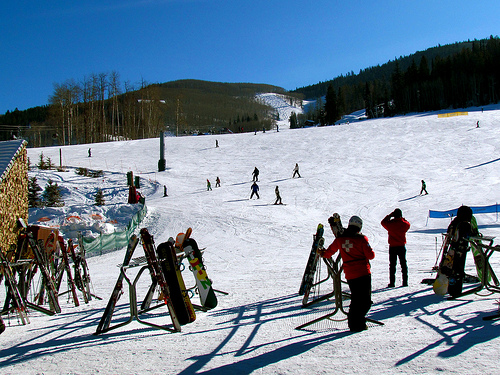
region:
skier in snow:
[267, 180, 287, 208]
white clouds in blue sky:
[134, 25, 161, 42]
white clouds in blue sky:
[287, 37, 342, 82]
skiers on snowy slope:
[185, 153, 307, 223]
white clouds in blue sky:
[327, 9, 355, 40]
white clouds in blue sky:
[172, 16, 209, 53]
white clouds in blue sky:
[124, 22, 161, 54]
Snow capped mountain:
[346, 129, 391, 177]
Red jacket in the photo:
[328, 223, 376, 275]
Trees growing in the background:
[325, 58, 441, 104]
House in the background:
[0, 132, 45, 231]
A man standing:
[315, 184, 378, 331]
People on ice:
[200, 143, 373, 211]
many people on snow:
[162, 125, 490, 355]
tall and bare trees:
[99, 86, 261, 137]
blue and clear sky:
[229, 1, 351, 68]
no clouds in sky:
[222, 14, 379, 106]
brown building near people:
[0, 139, 37, 229]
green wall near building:
[76, 169, 125, 276]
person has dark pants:
[337, 198, 372, 334]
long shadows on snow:
[206, 307, 343, 373]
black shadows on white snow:
[173, 303, 321, 374]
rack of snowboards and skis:
[85, 218, 230, 348]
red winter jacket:
[376, 211, 415, 250]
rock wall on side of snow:
[0, 135, 30, 285]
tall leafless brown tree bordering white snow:
[45, 70, 165, 147]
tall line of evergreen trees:
[315, 31, 495, 126]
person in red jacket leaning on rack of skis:
[291, 207, 381, 342]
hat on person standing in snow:
[345, 210, 365, 230]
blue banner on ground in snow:
[420, 200, 499, 232]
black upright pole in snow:
[153, 125, 171, 173]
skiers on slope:
[204, 161, 314, 216]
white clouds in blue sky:
[34, 5, 56, 39]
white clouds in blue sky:
[227, 29, 259, 59]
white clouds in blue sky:
[311, 21, 341, 65]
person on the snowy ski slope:
[322, 215, 374, 332]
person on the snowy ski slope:
[380, 205, 411, 285]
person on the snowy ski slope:
[290, 160, 300, 176]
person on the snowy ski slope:
[271, 180, 281, 205]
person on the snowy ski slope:
[250, 161, 260, 181]